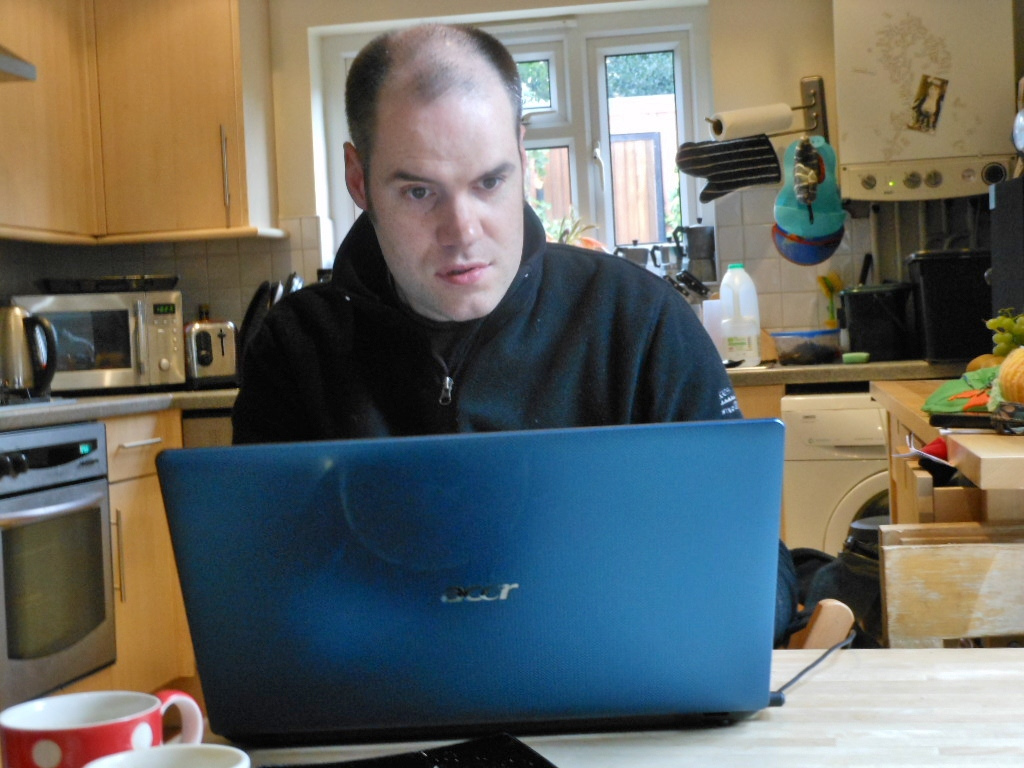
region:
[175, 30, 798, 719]
a man looking at a computer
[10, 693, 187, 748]
a mug on a table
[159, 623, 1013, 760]
a wooden table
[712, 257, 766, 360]
a bottle on the counter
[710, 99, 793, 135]
a roll of paper towels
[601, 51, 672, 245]
a window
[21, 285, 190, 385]
a silver microwave on the counter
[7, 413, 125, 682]
an oven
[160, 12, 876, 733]
Man with very thin hair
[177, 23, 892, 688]
Man seated in a kitchen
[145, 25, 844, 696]
Man wearing black sweater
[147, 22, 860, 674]
Man looking at laptop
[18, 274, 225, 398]
Silver microwave on a counter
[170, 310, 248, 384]
Silver toaster on a counter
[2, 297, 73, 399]
Silver coffee pot on stove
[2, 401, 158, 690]
Silver stove in the kitchen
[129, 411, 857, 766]
Laptop on a kitchen table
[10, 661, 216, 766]
Red coffee mug with white spots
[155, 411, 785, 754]
blue acer laptop on a table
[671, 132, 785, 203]
a black and grey striped oven mitt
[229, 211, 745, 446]
the black jumper of a man on the computer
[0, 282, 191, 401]
a microwave on a kitchen counter top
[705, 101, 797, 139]
a roll of paper towels hanging from the wall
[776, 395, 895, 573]
a washing machine in the kitchen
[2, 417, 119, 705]
an oven built into the cabinets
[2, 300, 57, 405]
a tea kettle on the stovetop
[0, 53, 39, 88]
a fan over the stove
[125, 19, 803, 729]
a white male on his laptop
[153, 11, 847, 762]
A man looking at a laptop screen.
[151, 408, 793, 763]
A blue laptop.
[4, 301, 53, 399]
A grey teapot with a black handle.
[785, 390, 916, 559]
A white washing machine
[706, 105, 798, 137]
A white roll of paper towels.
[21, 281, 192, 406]
A stainless steel microwave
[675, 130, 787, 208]
An oven mit.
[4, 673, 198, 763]
A polka dotted mug.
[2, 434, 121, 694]
a grey and black oven.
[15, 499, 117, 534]
handle on the oven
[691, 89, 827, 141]
paper towel on a roll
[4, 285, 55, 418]
a teapot on the stove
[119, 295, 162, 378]
a handle on the microwave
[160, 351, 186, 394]
a knob on the microwave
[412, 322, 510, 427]
a zipper on a jacket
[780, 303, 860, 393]
a bowl on the counter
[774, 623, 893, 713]
a computer cord on the table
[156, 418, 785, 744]
a blue laptop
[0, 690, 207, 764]
a red and white coffee mug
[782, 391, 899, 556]
washer under a counter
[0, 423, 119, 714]
an oven mounted under a cabinet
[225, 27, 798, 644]
a man using a laptop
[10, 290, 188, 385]
a white microwave on a counter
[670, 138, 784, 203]
a oven mitt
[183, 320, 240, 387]
a toaster on a counter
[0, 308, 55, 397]
a coffee pot on a stove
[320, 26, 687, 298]
window in a kitchen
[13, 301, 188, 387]
a silver microwave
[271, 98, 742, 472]
a man in a black jacket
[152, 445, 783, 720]
a black laptop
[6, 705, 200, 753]
a red mug on the table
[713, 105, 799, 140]
a roll of paper towels